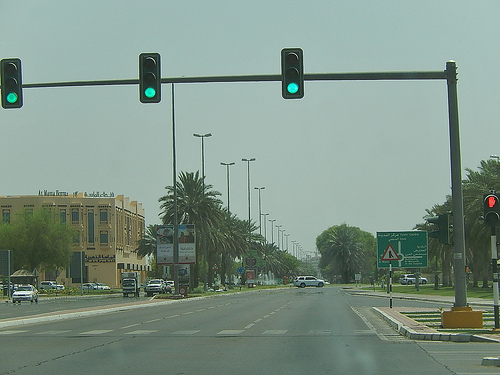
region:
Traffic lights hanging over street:
[0, 33, 360, 114]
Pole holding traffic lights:
[436, 53, 473, 330]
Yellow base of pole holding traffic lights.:
[433, 298, 490, 333]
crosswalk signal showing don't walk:
[477, 180, 498, 241]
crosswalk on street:
[1, 312, 389, 352]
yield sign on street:
[380, 240, 402, 310]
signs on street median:
[147, 211, 199, 269]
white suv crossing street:
[287, 263, 334, 291]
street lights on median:
[188, 120, 278, 237]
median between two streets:
[9, 300, 149, 334]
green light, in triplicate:
[1, 33, 485, 333]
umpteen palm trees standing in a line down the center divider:
[137, 175, 319, 301]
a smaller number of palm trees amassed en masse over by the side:
[405, 157, 497, 290]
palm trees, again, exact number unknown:
[316, 216, 391, 293]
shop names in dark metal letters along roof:
[30, 183, 116, 201]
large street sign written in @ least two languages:
[375, 227, 427, 294]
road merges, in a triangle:
[375, 241, 408, 312]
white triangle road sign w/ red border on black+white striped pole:
[377, 243, 402, 308]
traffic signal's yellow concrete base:
[433, 301, 488, 333]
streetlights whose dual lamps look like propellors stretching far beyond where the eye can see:
[187, 126, 322, 290]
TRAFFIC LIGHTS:
[0, 48, 318, 113]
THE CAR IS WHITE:
[11, 278, 50, 322]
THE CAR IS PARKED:
[3, 277, 50, 311]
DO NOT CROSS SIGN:
[468, 180, 499, 221]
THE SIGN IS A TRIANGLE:
[380, 244, 400, 270]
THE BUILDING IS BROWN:
[5, 180, 155, 312]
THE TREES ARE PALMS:
[161, 171, 313, 293]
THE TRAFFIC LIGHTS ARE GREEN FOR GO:
[3, 45, 313, 111]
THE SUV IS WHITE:
[292, 273, 330, 293]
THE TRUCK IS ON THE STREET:
[116, 266, 142, 300]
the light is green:
[0, 58, 37, 114]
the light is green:
[139, 83, 158, 108]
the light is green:
[276, 75, 308, 100]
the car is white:
[283, 266, 343, 299]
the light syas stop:
[473, 193, 497, 215]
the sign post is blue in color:
[380, 228, 434, 268]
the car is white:
[16, 282, 35, 304]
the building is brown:
[11, 188, 150, 286]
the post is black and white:
[383, 265, 398, 308]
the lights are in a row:
[178, 176, 325, 289]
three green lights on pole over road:
[0, 37, 384, 372]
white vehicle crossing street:
[248, 242, 355, 337]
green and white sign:
[370, 222, 460, 277]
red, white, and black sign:
[370, 236, 410, 268]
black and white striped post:
[373, 241, 409, 318]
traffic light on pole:
[419, 200, 487, 339]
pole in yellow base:
[418, 231, 490, 339]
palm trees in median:
[97, 166, 304, 313]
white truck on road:
[67, 254, 149, 315]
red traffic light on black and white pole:
[469, 185, 498, 322]